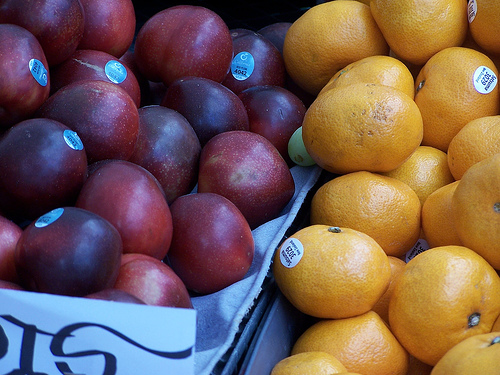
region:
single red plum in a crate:
[14, 205, 123, 295]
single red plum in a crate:
[113, 254, 192, 312]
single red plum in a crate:
[166, 192, 252, 295]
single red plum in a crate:
[76, 157, 168, 257]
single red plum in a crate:
[0, 115, 86, 217]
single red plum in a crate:
[0, 22, 50, 124]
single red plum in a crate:
[33, 78, 135, 163]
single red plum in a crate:
[131, 106, 201, 199]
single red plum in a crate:
[135, 4, 232, 86]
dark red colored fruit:
[1, 1, 88, 63]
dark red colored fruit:
[83, 0, 135, 51]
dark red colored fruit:
[138, 5, 228, 88]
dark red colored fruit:
[226, 31, 281, 94]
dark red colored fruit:
[244, 80, 299, 157]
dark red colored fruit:
[163, 74, 249, 141]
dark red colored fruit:
[63, 46, 140, 105]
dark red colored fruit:
[201, 133, 292, 225]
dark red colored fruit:
[132, 102, 202, 196]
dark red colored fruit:
[9, 120, 82, 215]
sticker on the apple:
[230, 47, 260, 81]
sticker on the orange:
[269, 236, 311, 272]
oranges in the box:
[258, 308, 375, 373]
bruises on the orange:
[366, 105, 408, 151]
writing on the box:
[21, 314, 166, 374]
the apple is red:
[221, 149, 258, 189]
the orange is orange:
[342, 116, 399, 161]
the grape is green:
[288, 130, 315, 177]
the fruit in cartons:
[64, 118, 426, 324]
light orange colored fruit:
[270, 218, 387, 320]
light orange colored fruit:
[293, 307, 401, 372]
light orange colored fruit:
[271, 346, 343, 372]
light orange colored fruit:
[391, 240, 491, 367]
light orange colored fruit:
[428, 329, 495, 374]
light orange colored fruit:
[298, 85, 423, 170]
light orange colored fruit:
[387, 144, 445, 195]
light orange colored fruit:
[440, 115, 499, 178]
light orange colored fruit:
[282, 2, 389, 92]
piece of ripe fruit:
[113, 245, 190, 317]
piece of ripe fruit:
[19, 197, 123, 287]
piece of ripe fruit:
[1, 110, 100, 217]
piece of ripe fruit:
[80, 151, 186, 262]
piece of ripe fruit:
[165, 184, 258, 299]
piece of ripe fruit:
[198, 117, 293, 231]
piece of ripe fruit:
[126, 95, 212, 194]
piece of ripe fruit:
[0, 20, 57, 120]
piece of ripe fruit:
[140, 5, 237, 95]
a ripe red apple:
[195, 129, 291, 219]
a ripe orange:
[397, 230, 494, 357]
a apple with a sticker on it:
[13, 120, 89, 195]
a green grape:
[284, 120, 311, 172]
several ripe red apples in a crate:
[32, 34, 271, 345]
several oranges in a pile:
[290, 6, 491, 369]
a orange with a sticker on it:
[415, 37, 498, 122]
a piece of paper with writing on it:
[6, 291, 205, 368]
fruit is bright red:
[79, 157, 170, 262]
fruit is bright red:
[170, 194, 255, 295]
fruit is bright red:
[200, 129, 296, 221]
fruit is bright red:
[236, 84, 306, 166]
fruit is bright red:
[168, 76, 249, 148]